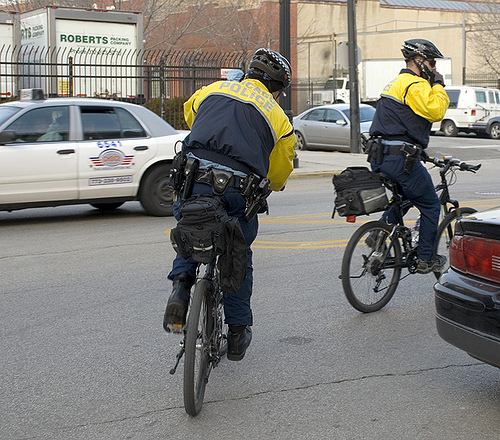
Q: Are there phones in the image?
A: Yes, there is a phone.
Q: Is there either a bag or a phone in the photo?
A: Yes, there is a phone.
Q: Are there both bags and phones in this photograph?
A: Yes, there are both a phone and a bag.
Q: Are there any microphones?
A: No, there are no microphones.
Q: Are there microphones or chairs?
A: No, there are no microphones or chairs.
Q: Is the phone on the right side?
A: Yes, the phone is on the right of the image.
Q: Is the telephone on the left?
A: No, the telephone is on the right of the image.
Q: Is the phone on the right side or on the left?
A: The phone is on the right of the image.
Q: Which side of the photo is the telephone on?
A: The telephone is on the right of the image.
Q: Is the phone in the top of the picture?
A: Yes, the phone is in the top of the image.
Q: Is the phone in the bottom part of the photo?
A: No, the phone is in the top of the image.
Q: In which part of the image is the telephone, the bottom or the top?
A: The telephone is in the top of the image.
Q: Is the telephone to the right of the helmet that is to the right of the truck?
A: Yes, the telephone is to the right of the helmet.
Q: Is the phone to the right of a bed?
A: No, the phone is to the right of the helmet.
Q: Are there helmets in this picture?
A: Yes, there is a helmet.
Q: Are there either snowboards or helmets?
A: Yes, there is a helmet.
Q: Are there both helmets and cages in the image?
A: No, there is a helmet but no cages.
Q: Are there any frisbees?
A: No, there are no frisbees.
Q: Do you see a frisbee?
A: No, there are no frisbees.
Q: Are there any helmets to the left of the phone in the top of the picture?
A: Yes, there is a helmet to the left of the telephone.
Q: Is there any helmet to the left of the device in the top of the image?
A: Yes, there is a helmet to the left of the telephone.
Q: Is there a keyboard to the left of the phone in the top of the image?
A: No, there is a helmet to the left of the phone.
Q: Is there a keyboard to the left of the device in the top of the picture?
A: No, there is a helmet to the left of the phone.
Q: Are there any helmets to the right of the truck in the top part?
A: Yes, there is a helmet to the right of the truck.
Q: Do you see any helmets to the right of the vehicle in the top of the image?
A: Yes, there is a helmet to the right of the truck.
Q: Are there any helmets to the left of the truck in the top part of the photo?
A: No, the helmet is to the right of the truck.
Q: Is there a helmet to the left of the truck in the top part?
A: No, the helmet is to the right of the truck.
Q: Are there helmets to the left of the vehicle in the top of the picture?
A: No, the helmet is to the right of the truck.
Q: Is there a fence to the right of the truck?
A: No, there is a helmet to the right of the truck.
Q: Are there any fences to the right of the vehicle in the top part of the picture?
A: No, there is a helmet to the right of the truck.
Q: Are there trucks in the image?
A: Yes, there is a truck.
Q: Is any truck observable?
A: Yes, there is a truck.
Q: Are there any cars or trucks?
A: Yes, there is a truck.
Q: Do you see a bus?
A: No, there are no buses.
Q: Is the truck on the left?
A: Yes, the truck is on the left of the image.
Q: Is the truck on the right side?
A: No, the truck is on the left of the image.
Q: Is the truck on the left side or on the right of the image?
A: The truck is on the left of the image.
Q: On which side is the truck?
A: The truck is on the left of the image.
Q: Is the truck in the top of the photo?
A: Yes, the truck is in the top of the image.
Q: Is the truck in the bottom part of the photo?
A: No, the truck is in the top of the image.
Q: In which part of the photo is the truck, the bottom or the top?
A: The truck is in the top of the image.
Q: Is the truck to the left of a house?
A: No, the truck is to the left of the helmet.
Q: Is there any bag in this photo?
A: Yes, there is a bag.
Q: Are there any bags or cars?
A: Yes, there is a bag.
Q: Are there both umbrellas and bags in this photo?
A: No, there is a bag but no umbrellas.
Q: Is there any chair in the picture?
A: No, there are no chairs.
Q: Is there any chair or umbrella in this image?
A: No, there are no chairs or umbrellas.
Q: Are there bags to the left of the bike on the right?
A: Yes, there is a bag to the left of the bike.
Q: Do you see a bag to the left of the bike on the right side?
A: Yes, there is a bag to the left of the bike.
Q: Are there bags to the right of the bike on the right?
A: No, the bag is to the left of the bike.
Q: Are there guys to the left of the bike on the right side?
A: No, there is a bag to the left of the bike.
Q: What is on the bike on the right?
A: The bag is on the bike.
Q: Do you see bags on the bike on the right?
A: Yes, there is a bag on the bike.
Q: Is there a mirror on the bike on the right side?
A: No, there is a bag on the bike.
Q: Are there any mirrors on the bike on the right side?
A: No, there is a bag on the bike.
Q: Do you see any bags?
A: Yes, there is a bag.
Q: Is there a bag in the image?
A: Yes, there is a bag.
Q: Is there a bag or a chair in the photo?
A: Yes, there is a bag.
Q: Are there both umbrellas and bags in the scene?
A: No, there is a bag but no umbrellas.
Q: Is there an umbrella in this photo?
A: No, there are no umbrellas.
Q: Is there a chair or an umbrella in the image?
A: No, there are no umbrellas or chairs.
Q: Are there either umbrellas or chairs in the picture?
A: No, there are no umbrellas or chairs.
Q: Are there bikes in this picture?
A: Yes, there is a bike.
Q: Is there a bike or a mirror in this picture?
A: Yes, there is a bike.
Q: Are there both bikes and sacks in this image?
A: No, there is a bike but no sacks.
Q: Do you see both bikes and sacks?
A: No, there is a bike but no sacks.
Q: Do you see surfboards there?
A: No, there are no surfboards.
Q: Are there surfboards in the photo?
A: No, there are no surfboards.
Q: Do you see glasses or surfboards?
A: No, there are no surfboards or glasses.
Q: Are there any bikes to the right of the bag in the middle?
A: Yes, there is a bike to the right of the bag.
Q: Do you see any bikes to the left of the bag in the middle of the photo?
A: No, the bike is to the right of the bag.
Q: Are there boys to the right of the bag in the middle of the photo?
A: No, there is a bike to the right of the bag.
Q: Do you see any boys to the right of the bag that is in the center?
A: No, there is a bike to the right of the bag.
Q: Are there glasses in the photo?
A: No, there are no glasses.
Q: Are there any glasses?
A: No, there are no glasses.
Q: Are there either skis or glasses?
A: No, there are no glasses or skis.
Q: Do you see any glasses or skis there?
A: No, there are no glasses or skis.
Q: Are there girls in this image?
A: No, there are no girls.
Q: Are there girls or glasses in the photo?
A: No, there are no girls or glasses.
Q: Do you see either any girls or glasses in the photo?
A: No, there are no girls or glasses.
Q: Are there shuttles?
A: No, there are no shuttles.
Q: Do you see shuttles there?
A: No, there are no shuttles.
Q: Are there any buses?
A: No, there are no buses.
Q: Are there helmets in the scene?
A: Yes, there is a helmet.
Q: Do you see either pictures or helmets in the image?
A: Yes, there is a helmet.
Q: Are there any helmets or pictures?
A: Yes, there is a helmet.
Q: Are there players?
A: No, there are no players.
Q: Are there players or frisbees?
A: No, there are no players or frisbees.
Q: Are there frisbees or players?
A: No, there are no players or frisbees.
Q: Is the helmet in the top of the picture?
A: Yes, the helmet is in the top of the image.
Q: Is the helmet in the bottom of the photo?
A: No, the helmet is in the top of the image.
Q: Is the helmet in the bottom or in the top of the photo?
A: The helmet is in the top of the image.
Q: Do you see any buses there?
A: No, there are no buses.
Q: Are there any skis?
A: No, there are no skis.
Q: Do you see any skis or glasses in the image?
A: No, there are no skis or glasses.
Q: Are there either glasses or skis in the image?
A: No, there are no skis or glasses.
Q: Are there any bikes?
A: Yes, there is a bike.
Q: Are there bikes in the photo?
A: Yes, there is a bike.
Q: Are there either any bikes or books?
A: Yes, there is a bike.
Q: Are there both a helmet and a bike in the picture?
A: Yes, there are both a bike and a helmet.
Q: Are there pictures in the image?
A: No, there are no pictures.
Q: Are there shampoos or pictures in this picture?
A: No, there are no pictures or shampoos.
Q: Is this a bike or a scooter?
A: This is a bike.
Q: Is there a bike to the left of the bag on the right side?
A: Yes, there is a bike to the left of the bag.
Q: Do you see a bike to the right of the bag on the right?
A: No, the bike is to the left of the bag.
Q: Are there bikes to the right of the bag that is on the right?
A: No, the bike is to the left of the bag.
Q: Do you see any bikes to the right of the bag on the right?
A: No, the bike is to the left of the bag.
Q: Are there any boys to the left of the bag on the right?
A: No, there is a bike to the left of the bag.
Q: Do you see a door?
A: Yes, there is a door.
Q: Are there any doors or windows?
A: Yes, there is a door.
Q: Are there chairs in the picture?
A: No, there are no chairs.